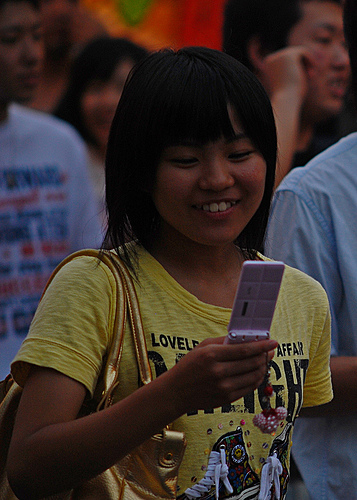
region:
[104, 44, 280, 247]
Smiling face of a girl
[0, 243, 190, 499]
Shiny gold colored handbag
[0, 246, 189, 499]
Bag hanging under the shoulders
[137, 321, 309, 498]
Branding on a shirt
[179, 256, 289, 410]
Cell phone held in the hand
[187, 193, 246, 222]
Open mouth with white teeth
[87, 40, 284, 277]
Head with dark black hair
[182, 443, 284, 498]
White laces on the shirt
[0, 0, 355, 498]
Group of people walking in a direction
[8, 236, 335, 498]
Short sleeved yellow shirt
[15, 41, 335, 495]
A young woman using a cellphone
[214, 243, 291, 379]
Flip phone in woman's hand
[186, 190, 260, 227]
Smile on woman's face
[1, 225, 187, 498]
Gold purse on woman's shoulder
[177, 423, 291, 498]
Pictures of shoes on woman's shirt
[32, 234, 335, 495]
Woman is wearing yellow shirt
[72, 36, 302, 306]
Woman has short black hair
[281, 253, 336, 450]
Woman is missing an arm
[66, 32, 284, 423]
Woman is smiling at phone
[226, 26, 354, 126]
Man talking on cell phone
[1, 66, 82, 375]
Man wearing white shirt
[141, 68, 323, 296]
a woman that is outside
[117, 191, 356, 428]
a woman wearing a shirt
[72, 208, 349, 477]
a woman wearing a white shirt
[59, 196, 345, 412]
a person wearing a yellow shirt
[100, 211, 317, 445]
a person on a phone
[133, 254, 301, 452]
a person on a cell phone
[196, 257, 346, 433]
a person holidng a phone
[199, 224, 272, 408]
a person holding a cell phone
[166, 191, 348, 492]
a person holding a flip phone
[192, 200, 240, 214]
the woman is smiling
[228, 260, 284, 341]
the woman holds a phone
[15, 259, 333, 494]
the woman wears a yellow shirt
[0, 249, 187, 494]
the woman holds a gold purse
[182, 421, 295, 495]
the shirt has sneakers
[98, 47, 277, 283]
the woman has short hair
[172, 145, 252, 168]
woman looks at phone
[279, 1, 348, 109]
a man is on the phone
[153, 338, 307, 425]
the shirt has words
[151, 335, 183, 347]
shirt says love on it